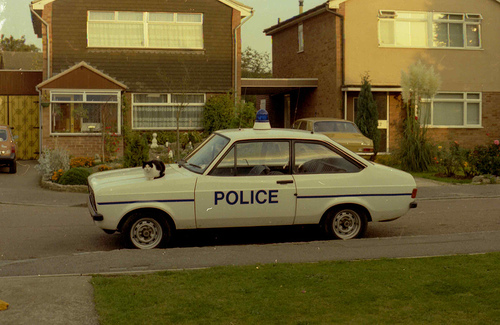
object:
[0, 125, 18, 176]
car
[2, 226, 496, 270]
sidewalk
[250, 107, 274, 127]
siren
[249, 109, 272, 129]
light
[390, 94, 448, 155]
wall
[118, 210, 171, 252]
tire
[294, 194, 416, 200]
stripe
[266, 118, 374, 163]
car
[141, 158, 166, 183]
cat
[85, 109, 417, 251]
police car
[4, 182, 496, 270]
street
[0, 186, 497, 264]
roadway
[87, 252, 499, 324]
grass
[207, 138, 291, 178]
windows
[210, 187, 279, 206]
black letters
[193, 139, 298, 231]
door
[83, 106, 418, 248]
car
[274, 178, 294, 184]
handle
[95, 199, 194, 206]
stripe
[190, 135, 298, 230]
car door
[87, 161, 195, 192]
hood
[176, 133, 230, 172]
windshield